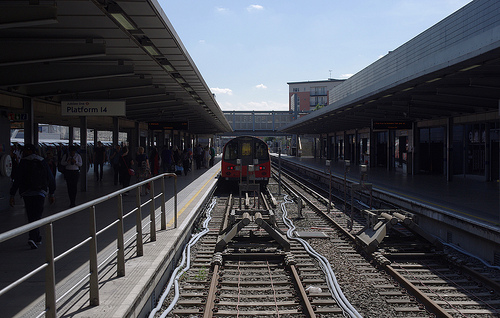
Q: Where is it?
A: This is at the station.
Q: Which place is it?
A: It is a station.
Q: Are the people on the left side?
A: Yes, the people are on the left of the image.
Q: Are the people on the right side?
A: No, the people are on the left of the image.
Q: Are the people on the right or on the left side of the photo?
A: The people are on the left of the image.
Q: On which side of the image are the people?
A: The people are on the left of the image.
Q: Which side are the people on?
A: The people are on the left of the image.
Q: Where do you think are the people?
A: The people are on the walkway.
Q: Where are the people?
A: The people are on the walkway.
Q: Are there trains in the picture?
A: Yes, there is a train.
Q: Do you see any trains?
A: Yes, there is a train.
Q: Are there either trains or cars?
A: Yes, there is a train.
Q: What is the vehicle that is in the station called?
A: The vehicle is a train.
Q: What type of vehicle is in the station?
A: The vehicle is a train.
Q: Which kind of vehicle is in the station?
A: The vehicle is a train.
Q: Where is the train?
A: The train is in the station.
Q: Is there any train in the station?
A: Yes, there is a train in the station.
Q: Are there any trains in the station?
A: Yes, there is a train in the station.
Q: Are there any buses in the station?
A: No, there is a train in the station.